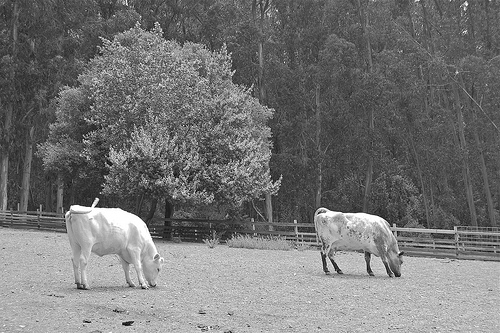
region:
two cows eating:
[49, 203, 404, 287]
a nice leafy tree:
[48, 44, 277, 209]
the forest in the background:
[292, 52, 492, 209]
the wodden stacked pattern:
[413, 227, 498, 263]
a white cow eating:
[65, 202, 164, 290]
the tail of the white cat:
[68, 197, 100, 215]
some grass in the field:
[206, 228, 289, 254]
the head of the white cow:
[143, 255, 163, 288]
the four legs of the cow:
[71, 247, 145, 290]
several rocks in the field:
[83, 303, 234, 331]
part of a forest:
[451, 190, 466, 209]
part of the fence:
[431, 239, 439, 246]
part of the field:
[273, 293, 293, 320]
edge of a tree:
[213, 163, 237, 203]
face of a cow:
[150, 260, 157, 268]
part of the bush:
[247, 228, 257, 245]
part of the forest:
[369, 166, 393, 198]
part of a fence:
[434, 233, 441, 247]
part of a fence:
[455, 243, 460, 249]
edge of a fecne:
[427, 251, 432, 276]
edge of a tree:
[179, 97, 193, 114]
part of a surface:
[292, 285, 310, 293]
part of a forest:
[351, 170, 367, 202]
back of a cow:
[333, 221, 342, 230]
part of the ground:
[242, 250, 257, 272]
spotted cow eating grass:
[312, 196, 413, 281]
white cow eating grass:
[58, 198, 173, 291]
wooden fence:
[3, 203, 497, 255]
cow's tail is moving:
[68, 190, 103, 217]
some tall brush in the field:
[199, 226, 308, 253]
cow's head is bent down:
[139, 238, 175, 294]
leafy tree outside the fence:
[52, 22, 284, 252]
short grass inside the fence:
[3, 244, 498, 329]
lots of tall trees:
[4, 4, 498, 236]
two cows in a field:
[57, 185, 415, 297]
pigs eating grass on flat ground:
[62, 201, 404, 288]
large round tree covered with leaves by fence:
[42, 27, 273, 241]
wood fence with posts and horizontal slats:
[0, 202, 498, 259]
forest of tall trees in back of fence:
[5, 2, 495, 227]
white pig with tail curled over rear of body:
[64, 193, 159, 286]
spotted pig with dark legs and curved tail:
[311, 205, 403, 278]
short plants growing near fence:
[196, 230, 291, 246]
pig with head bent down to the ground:
[61, 205, 165, 291]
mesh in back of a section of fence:
[459, 223, 497, 261]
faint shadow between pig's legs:
[63, 198, 160, 289]